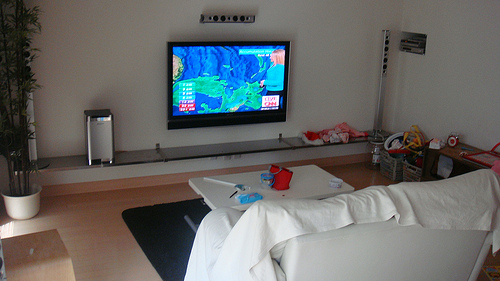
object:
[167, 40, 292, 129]
tv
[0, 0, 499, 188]
wall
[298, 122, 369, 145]
clothes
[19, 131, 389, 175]
shelf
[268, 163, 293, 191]
bag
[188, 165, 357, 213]
table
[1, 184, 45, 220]
pot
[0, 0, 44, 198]
plant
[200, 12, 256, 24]
speaker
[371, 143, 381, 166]
bucket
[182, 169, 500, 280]
cover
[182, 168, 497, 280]
couch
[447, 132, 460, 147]
alarm clock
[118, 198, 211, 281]
rug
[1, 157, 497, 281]
floor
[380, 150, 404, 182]
carton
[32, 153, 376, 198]
trim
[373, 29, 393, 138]
speaker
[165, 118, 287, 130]
edge